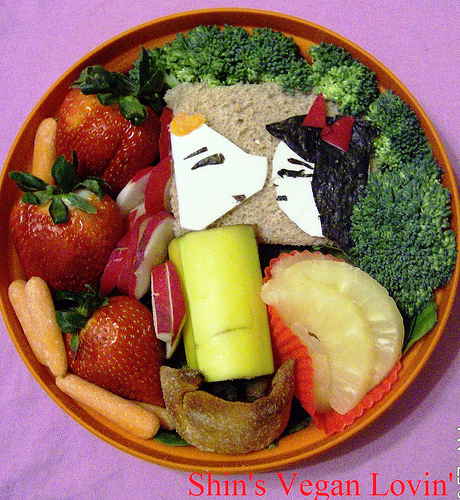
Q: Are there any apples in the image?
A: Yes, there is an apple.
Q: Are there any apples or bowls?
A: Yes, there is an apple.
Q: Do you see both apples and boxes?
A: No, there is an apple but no boxes.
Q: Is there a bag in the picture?
A: No, there are no bags.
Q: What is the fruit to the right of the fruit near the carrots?
A: The fruit is an apple.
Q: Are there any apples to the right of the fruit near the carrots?
A: Yes, there is an apple to the right of the fruit.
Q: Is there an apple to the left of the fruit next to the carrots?
A: No, the apple is to the right of the fruit.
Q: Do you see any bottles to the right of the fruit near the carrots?
A: No, there is an apple to the right of the fruit.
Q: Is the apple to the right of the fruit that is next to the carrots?
A: Yes, the apple is to the right of the fruit.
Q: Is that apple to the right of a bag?
A: No, the apple is to the right of the fruit.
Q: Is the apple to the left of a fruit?
A: No, the apple is to the right of a fruit.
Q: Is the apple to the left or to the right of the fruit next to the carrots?
A: The apple is to the right of the fruit.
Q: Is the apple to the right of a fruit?
A: No, the apple is to the left of a fruit.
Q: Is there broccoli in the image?
A: Yes, there is broccoli.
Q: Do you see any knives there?
A: No, there are no knives.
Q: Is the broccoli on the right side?
A: Yes, the broccoli is on the right of the image.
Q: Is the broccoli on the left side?
A: No, the broccoli is on the right of the image.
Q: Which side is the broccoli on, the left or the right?
A: The broccoli is on the right of the image.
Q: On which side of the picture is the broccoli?
A: The broccoli is on the right of the image.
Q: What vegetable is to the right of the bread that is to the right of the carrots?
A: The vegetable is broccoli.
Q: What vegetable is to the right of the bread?
A: The vegetable is broccoli.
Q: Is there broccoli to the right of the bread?
A: Yes, there is broccoli to the right of the bread.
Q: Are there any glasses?
A: No, there are no glasses.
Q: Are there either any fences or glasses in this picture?
A: No, there are no glasses or fences.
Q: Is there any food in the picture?
A: Yes, there is food.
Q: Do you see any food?
A: Yes, there is food.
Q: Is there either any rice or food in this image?
A: Yes, there is food.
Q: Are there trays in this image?
A: No, there are no trays.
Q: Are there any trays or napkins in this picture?
A: No, there are no trays or napkins.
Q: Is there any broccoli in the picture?
A: Yes, there is broccoli.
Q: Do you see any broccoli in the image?
A: Yes, there is broccoli.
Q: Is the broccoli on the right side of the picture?
A: Yes, the broccoli is on the right of the image.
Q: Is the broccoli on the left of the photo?
A: No, the broccoli is on the right of the image.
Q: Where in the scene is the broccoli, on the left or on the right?
A: The broccoli is on the right of the image.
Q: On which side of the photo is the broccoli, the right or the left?
A: The broccoli is on the right of the image.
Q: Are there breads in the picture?
A: Yes, there is a bread.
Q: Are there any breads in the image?
A: Yes, there is a bread.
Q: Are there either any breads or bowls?
A: Yes, there is a bread.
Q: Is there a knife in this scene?
A: No, there are no knives.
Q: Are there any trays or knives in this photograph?
A: No, there are no knives or trays.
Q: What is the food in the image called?
A: The food is a bread.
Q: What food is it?
A: The food is a bread.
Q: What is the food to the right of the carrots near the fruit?
A: The food is a bread.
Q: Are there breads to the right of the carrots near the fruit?
A: Yes, there is a bread to the right of the carrots.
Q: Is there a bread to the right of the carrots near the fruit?
A: Yes, there is a bread to the right of the carrots.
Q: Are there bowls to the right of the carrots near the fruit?
A: No, there is a bread to the right of the carrots.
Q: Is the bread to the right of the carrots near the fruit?
A: Yes, the bread is to the right of the carrots.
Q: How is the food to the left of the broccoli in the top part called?
A: The food is a bread.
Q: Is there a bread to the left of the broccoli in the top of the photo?
A: Yes, there is a bread to the left of the broccoli.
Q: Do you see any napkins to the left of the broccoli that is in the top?
A: No, there is a bread to the left of the broccoli.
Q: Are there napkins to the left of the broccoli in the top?
A: No, there is a bread to the left of the broccoli.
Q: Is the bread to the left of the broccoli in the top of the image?
A: Yes, the bread is to the left of the broccoli.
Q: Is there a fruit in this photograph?
A: Yes, there is a fruit.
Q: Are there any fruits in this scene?
A: Yes, there is a fruit.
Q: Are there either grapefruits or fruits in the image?
A: Yes, there is a fruit.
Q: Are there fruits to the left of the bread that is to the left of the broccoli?
A: Yes, there is a fruit to the left of the bread.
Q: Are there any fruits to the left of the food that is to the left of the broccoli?
A: Yes, there is a fruit to the left of the bread.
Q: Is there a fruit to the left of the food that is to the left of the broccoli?
A: Yes, there is a fruit to the left of the bread.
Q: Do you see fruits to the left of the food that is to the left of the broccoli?
A: Yes, there is a fruit to the left of the bread.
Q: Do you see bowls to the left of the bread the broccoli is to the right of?
A: No, there is a fruit to the left of the bread.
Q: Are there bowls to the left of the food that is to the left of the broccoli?
A: No, there is a fruit to the left of the bread.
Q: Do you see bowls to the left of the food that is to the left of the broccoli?
A: No, there is a fruit to the left of the bread.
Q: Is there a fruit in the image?
A: Yes, there is a fruit.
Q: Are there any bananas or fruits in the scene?
A: Yes, there is a fruit.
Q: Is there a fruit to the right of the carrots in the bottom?
A: Yes, there is a fruit to the right of the carrots.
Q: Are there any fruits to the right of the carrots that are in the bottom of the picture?
A: Yes, there is a fruit to the right of the carrots.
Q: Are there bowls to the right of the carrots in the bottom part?
A: No, there is a fruit to the right of the carrots.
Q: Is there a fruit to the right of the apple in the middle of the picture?
A: Yes, there is a fruit to the right of the apple.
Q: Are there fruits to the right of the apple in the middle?
A: Yes, there is a fruit to the right of the apple.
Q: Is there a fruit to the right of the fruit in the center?
A: Yes, there is a fruit to the right of the apple.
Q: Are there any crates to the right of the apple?
A: No, there is a fruit to the right of the apple.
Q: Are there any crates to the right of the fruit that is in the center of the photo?
A: No, there is a fruit to the right of the apple.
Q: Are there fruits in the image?
A: Yes, there is a fruit.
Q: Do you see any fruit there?
A: Yes, there is a fruit.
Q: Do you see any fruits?
A: Yes, there is a fruit.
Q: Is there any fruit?
A: Yes, there is a fruit.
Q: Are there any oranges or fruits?
A: Yes, there is a fruit.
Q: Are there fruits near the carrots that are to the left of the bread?
A: Yes, there is a fruit near the carrots.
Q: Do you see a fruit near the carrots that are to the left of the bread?
A: Yes, there is a fruit near the carrots.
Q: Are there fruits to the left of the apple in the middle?
A: Yes, there is a fruit to the left of the apple.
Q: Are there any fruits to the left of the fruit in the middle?
A: Yes, there is a fruit to the left of the apple.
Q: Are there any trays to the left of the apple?
A: No, there is a fruit to the left of the apple.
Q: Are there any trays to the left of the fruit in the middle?
A: No, there is a fruit to the left of the apple.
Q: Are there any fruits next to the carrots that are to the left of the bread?
A: Yes, there is a fruit next to the carrots.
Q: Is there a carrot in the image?
A: Yes, there are carrots.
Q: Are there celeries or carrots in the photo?
A: Yes, there are carrots.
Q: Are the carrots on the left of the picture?
A: Yes, the carrots are on the left of the image.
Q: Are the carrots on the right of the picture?
A: No, the carrots are on the left of the image.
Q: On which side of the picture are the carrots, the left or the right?
A: The carrots are on the left of the image.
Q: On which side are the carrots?
A: The carrots are on the left of the image.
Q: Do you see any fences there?
A: No, there are no fences.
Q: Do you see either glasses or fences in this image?
A: No, there are no fences or glasses.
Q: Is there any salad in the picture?
A: Yes, there is salad.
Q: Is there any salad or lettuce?
A: Yes, there is salad.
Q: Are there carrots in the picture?
A: Yes, there are carrots.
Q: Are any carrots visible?
A: Yes, there are carrots.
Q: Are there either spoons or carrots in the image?
A: Yes, there are carrots.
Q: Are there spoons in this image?
A: No, there are no spoons.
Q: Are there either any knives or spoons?
A: No, there are no spoons or knives.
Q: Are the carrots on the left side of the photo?
A: Yes, the carrots are on the left of the image.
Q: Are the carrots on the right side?
A: No, the carrots are on the left of the image.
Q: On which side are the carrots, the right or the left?
A: The carrots are on the left of the image.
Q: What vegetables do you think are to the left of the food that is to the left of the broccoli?
A: The vegetables are carrots.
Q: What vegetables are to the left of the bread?
A: The vegetables are carrots.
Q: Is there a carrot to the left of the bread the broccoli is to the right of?
A: Yes, there are carrots to the left of the bread.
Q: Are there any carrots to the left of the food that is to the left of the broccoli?
A: Yes, there are carrots to the left of the bread.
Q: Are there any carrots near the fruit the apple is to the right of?
A: Yes, there are carrots near the fruit.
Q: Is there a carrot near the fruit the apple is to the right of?
A: Yes, there are carrots near the fruit.